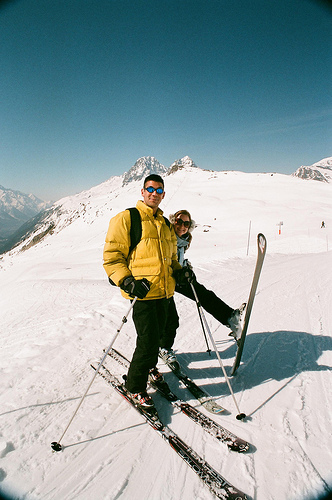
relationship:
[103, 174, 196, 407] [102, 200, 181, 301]
man in jacket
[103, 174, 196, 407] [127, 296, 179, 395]
man in black pants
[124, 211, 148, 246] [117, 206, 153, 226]
strap around shoulder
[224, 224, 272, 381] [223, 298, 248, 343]
ski on foot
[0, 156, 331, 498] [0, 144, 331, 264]
snow on rocky terrain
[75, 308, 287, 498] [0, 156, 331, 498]
ski marks in snow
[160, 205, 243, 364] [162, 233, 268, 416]
person standing on skis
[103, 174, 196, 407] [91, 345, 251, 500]
man standing on ski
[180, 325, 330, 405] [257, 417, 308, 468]
shadow of skiers on snow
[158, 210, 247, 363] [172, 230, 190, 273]
person in a jacket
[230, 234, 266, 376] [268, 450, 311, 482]
ski sticking upright snow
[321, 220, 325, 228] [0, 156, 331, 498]
person walking on snow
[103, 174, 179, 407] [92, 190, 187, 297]
man wearing jacket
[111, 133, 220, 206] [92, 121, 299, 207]
outcrops on top of mountain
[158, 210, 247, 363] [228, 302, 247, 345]
person with foot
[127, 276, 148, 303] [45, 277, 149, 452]
hand around handle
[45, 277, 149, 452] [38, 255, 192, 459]
handle of pole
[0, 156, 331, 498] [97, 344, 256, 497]
snow on ski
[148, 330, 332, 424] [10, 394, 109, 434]
shadow in snow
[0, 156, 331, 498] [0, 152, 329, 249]
snow on mountain